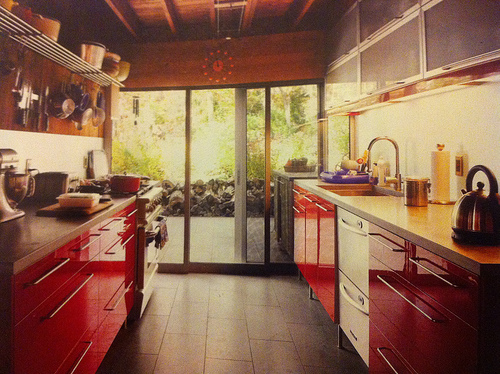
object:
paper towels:
[429, 133, 451, 205]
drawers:
[1, 193, 138, 374]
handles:
[30, 257, 71, 284]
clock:
[198, 45, 238, 86]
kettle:
[451, 165, 500, 245]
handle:
[460, 159, 494, 195]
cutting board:
[37, 192, 118, 215]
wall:
[1, 35, 122, 191]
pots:
[70, 104, 96, 125]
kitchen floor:
[128, 264, 337, 371]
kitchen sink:
[317, 178, 402, 198]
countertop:
[267, 171, 497, 274]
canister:
[404, 176, 430, 208]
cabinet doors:
[288, 185, 339, 322]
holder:
[427, 137, 452, 162]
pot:
[42, 82, 81, 120]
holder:
[315, 160, 371, 184]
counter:
[290, 178, 500, 374]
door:
[182, 82, 269, 272]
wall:
[94, 25, 328, 89]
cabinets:
[367, 223, 500, 372]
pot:
[73, 35, 115, 73]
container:
[54, 191, 100, 212]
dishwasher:
[333, 202, 367, 370]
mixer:
[0, 147, 36, 227]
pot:
[104, 175, 144, 199]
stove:
[64, 169, 155, 201]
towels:
[429, 147, 449, 207]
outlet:
[451, 155, 465, 177]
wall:
[346, 70, 498, 214]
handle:
[375, 272, 440, 323]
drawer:
[365, 221, 489, 373]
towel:
[156, 218, 173, 250]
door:
[137, 201, 162, 291]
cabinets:
[0, 197, 147, 374]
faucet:
[365, 135, 401, 193]